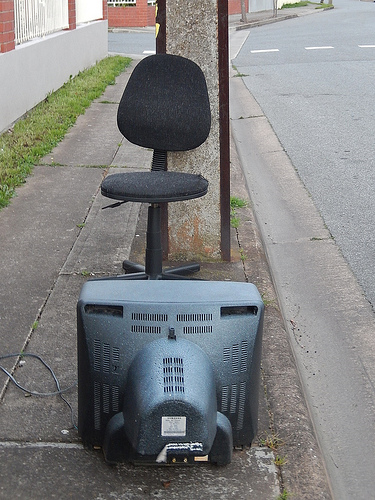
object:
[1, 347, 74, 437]
cord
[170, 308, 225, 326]
vent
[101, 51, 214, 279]
chair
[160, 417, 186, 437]
tag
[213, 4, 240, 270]
metal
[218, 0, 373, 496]
road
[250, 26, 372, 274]
street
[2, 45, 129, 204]
median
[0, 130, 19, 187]
grass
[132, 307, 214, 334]
holes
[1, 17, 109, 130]
fence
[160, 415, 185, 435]
lable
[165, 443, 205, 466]
cable jacks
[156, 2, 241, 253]
post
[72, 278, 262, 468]
television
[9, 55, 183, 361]
sidewalk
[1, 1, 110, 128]
building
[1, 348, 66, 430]
power cord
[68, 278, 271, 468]
television set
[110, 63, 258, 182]
cushion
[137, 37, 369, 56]
area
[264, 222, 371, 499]
pavement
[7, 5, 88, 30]
fence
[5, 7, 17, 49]
brick